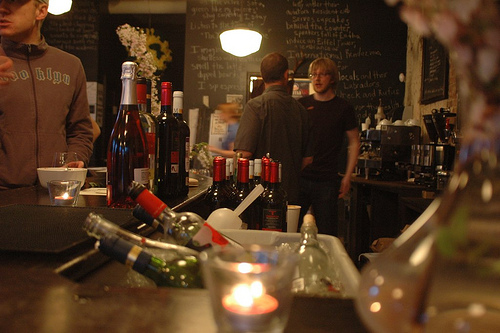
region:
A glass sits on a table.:
[192, 222, 309, 331]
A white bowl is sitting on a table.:
[28, 159, 95, 197]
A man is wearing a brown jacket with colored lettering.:
[0, 0, 110, 215]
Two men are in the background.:
[225, 46, 365, 248]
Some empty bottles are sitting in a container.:
[74, 173, 371, 310]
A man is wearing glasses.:
[297, 59, 342, 98]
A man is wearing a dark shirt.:
[287, 81, 362, 189]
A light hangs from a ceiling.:
[205, 1, 277, 74]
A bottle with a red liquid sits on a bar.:
[97, 55, 164, 217]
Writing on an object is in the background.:
[172, 0, 435, 175]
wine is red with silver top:
[101, 46, 196, 285]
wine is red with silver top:
[83, 42, 170, 194]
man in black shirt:
[231, 38, 372, 268]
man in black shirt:
[296, 47, 376, 274]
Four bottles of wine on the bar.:
[95, 46, 194, 208]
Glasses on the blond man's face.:
[307, 69, 342, 81]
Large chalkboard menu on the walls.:
[1, 0, 416, 167]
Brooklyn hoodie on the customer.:
[1, 30, 106, 200]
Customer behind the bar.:
[3, 11, 108, 201]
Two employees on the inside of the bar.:
[217, 35, 380, 262]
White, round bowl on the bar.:
[29, 161, 96, 198]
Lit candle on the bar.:
[160, 228, 310, 328]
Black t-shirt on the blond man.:
[272, 87, 377, 187]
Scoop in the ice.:
[192, 176, 284, 233]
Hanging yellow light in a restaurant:
[214, 24, 264, 61]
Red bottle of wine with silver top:
[107, 59, 147, 210]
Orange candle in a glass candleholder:
[193, 236, 290, 331]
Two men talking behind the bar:
[250, 44, 347, 191]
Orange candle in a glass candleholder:
[45, 172, 89, 210]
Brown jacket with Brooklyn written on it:
[0, 56, 100, 180]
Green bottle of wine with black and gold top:
[79, 229, 204, 296]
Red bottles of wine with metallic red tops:
[202, 150, 289, 227]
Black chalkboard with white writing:
[198, 12, 408, 62]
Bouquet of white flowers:
[112, 15, 164, 87]